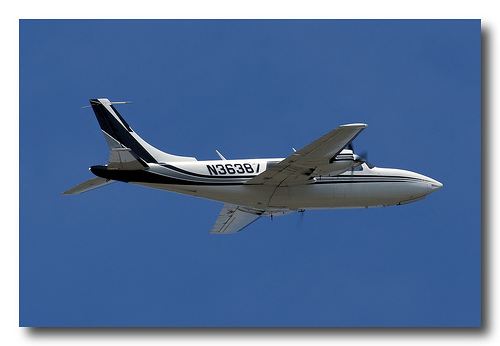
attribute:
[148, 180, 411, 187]
stripe — black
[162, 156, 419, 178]
stripe — black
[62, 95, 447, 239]
plane — small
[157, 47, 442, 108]
sky — blue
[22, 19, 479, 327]
clouds — white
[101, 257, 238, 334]
clouds — white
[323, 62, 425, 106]
sky — blue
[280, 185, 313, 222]
engine — small, propeller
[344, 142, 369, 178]
propeller — small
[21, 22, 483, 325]
sky — blue, small patch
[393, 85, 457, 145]
clouds — white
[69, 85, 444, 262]
plane — small, white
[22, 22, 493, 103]
sky — small patch, blue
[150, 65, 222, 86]
clouds — white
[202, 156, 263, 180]
number — identification